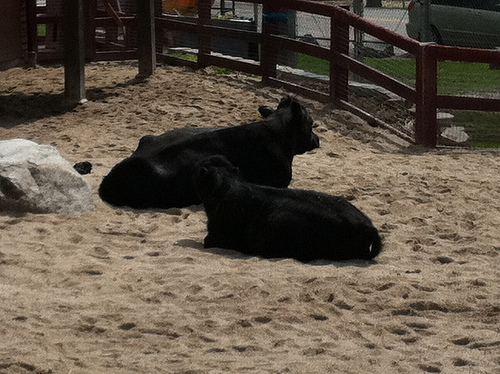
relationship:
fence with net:
[33, 3, 499, 143] [360, 40, 387, 65]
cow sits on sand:
[190, 155, 383, 264] [10, 55, 493, 361]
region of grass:
[32, 8, 496, 145] [35, 20, 497, 146]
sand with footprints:
[7, 239, 469, 369] [389, 287, 431, 325]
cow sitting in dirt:
[190, 155, 383, 264] [0, 55, 499, 372]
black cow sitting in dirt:
[105, 62, 322, 225] [41, 180, 195, 344]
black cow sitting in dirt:
[98, 95, 319, 209] [51, 115, 437, 370]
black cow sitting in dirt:
[98, 95, 319, 209] [96, 198, 206, 271]